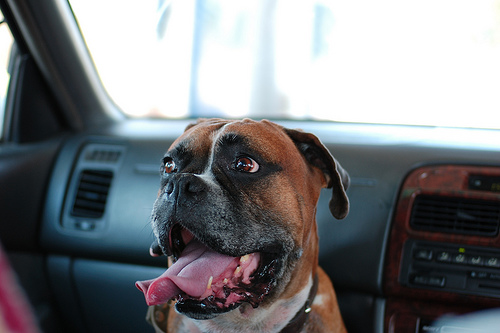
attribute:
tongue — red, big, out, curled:
[144, 256, 220, 291]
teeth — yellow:
[224, 258, 263, 277]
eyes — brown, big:
[223, 158, 264, 178]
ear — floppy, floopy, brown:
[287, 126, 353, 223]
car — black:
[103, 72, 494, 271]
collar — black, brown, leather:
[296, 281, 310, 332]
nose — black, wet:
[162, 167, 202, 196]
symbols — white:
[410, 246, 491, 274]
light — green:
[452, 237, 472, 257]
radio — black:
[421, 275, 495, 292]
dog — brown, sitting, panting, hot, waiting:
[136, 102, 259, 332]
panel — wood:
[426, 164, 497, 327]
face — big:
[171, 123, 301, 243]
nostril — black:
[167, 166, 213, 202]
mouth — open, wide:
[148, 205, 259, 307]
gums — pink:
[222, 284, 238, 309]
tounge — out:
[155, 259, 186, 300]